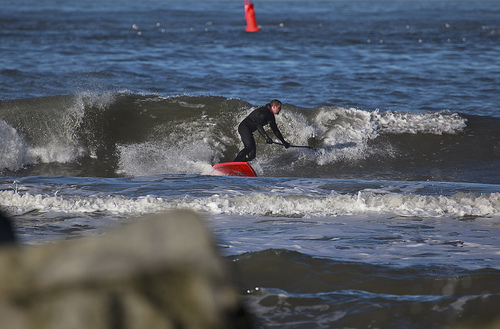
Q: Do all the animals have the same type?
A: Yes, all the animals are birds.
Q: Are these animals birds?
A: Yes, all the animals are birds.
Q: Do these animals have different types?
A: No, all the animals are birds.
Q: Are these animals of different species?
A: No, all the animals are birds.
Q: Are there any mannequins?
A: No, there are no mannequins.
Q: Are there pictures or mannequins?
A: No, there are no mannequins or pictures.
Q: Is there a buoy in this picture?
A: Yes, there is a buoy.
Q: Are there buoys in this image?
A: Yes, there is a buoy.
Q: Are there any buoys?
A: Yes, there is a buoy.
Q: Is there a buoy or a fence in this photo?
A: Yes, there is a buoy.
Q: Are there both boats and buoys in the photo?
A: No, there is a buoy but no boats.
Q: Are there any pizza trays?
A: No, there are no pizza trays.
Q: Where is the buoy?
A: The buoy is in the water.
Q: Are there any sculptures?
A: No, there are no sculptures.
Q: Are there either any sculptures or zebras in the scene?
A: No, there are no sculptures or zebras.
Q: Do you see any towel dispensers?
A: No, there are no towel dispensers.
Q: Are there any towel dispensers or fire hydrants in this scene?
A: No, there are no towel dispensers or fire hydrants.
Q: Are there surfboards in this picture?
A: Yes, there is a surfboard.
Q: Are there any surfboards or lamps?
A: Yes, there is a surfboard.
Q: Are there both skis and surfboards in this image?
A: No, there is a surfboard but no skis.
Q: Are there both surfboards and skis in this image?
A: No, there is a surfboard but no skis.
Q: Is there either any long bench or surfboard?
A: Yes, there is a long surfboard.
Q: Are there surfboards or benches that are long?
A: Yes, the surfboard is long.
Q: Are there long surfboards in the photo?
A: Yes, there is a long surfboard.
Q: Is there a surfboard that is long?
A: Yes, there is a surfboard that is long.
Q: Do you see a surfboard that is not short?
A: Yes, there is a long surfboard.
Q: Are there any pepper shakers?
A: No, there are no pepper shakers.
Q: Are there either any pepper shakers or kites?
A: No, there are no pepper shakers or kites.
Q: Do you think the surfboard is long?
A: Yes, the surfboard is long.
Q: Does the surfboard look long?
A: Yes, the surfboard is long.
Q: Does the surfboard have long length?
A: Yes, the surfboard is long.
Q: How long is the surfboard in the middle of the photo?
A: The surf board is long.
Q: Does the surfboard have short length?
A: No, the surfboard is long.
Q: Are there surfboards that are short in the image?
A: No, there is a surfboard but it is long.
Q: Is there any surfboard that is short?
A: No, there is a surfboard but it is long.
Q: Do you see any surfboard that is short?
A: No, there is a surfboard but it is long.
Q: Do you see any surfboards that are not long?
A: No, there is a surfboard but it is long.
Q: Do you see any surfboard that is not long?
A: No, there is a surfboard but it is long.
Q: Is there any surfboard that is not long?
A: No, there is a surfboard but it is long.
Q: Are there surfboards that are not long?
A: No, there is a surfboard but it is long.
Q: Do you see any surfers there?
A: Yes, there is a surfer.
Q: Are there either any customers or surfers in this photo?
A: Yes, there is a surfer.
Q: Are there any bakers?
A: No, there are no bakers.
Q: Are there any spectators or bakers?
A: No, there are no bakers or spectators.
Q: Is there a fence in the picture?
A: No, there are no fences.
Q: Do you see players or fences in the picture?
A: No, there are no fences or players.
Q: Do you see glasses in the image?
A: No, there are no glasses.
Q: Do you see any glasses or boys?
A: No, there are no glasses or boys.